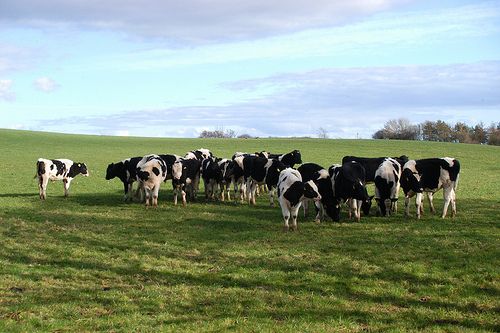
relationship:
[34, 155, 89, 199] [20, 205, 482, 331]
cow standing on field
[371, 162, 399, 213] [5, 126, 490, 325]
cow standing on field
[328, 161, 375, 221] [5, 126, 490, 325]
cow standing on field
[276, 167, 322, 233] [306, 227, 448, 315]
cow standing on field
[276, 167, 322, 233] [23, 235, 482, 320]
cow standing on field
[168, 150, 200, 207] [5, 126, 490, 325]
cow standing on field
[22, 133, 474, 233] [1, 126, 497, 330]
cattle on grass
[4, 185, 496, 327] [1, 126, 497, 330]
shadows on grass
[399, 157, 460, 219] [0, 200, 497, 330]
cow in field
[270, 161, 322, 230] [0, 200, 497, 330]
cow in field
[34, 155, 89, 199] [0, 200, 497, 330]
cow in field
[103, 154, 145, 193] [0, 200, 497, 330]
cow in field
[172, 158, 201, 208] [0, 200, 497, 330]
cow in field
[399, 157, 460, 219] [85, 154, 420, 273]
cow in field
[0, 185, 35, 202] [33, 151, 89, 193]
shadow of cow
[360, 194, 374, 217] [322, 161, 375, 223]
head belonging to cow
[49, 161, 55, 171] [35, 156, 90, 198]
spot covering cow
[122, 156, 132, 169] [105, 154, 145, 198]
spot covering cow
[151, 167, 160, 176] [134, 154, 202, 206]
spot covering cow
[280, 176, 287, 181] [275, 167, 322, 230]
spot covering cow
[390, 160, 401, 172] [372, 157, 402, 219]
spot covering cow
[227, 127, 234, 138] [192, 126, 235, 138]
tree standing in group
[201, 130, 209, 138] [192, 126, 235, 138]
tree standing in group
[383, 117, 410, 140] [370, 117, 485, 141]
tree standing in group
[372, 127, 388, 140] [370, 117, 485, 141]
tree standing in group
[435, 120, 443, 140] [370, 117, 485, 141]
tree standing in group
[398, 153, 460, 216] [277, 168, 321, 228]
cow with cow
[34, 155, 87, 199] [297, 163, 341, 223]
cow with cow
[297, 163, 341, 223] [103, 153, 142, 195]
cow with cow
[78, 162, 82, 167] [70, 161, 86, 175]
tag on ear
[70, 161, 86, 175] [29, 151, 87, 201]
ear of cow